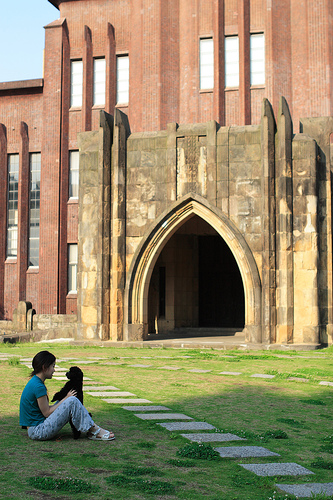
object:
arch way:
[157, 242, 225, 342]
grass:
[111, 348, 325, 491]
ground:
[258, 106, 287, 127]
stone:
[232, 152, 296, 210]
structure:
[56, 103, 331, 489]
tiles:
[1, 350, 331, 498]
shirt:
[18, 373, 52, 422]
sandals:
[92, 425, 116, 441]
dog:
[49, 363, 82, 405]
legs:
[66, 419, 78, 434]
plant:
[169, 431, 225, 470]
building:
[47, 12, 327, 248]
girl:
[17, 349, 115, 442]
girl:
[18, 344, 118, 446]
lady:
[6, 346, 123, 455]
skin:
[23, 425, 31, 431]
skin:
[36, 393, 53, 413]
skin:
[39, 371, 54, 379]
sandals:
[85, 419, 117, 445]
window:
[249, 30, 265, 88]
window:
[223, 31, 241, 90]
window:
[197, 36, 215, 93]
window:
[115, 52, 129, 107]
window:
[92, 53, 107, 107]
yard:
[1, 343, 332, 498]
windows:
[6, 153, 19, 269]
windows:
[63, 149, 79, 294]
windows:
[66, 55, 80, 106]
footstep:
[142, 410, 275, 485]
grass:
[0, 341, 331, 497]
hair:
[27, 350, 57, 377]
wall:
[1, 1, 330, 348]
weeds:
[28, 471, 102, 497]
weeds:
[104, 471, 176, 496]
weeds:
[177, 441, 221, 461]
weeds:
[263, 425, 287, 442]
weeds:
[310, 454, 331, 470]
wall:
[145, 23, 189, 95]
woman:
[19, 350, 116, 441]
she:
[17, 348, 118, 442]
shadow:
[1, 409, 331, 497]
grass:
[5, 442, 121, 495]